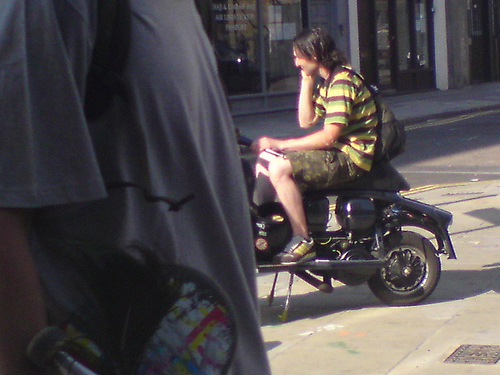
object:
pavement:
[256, 181, 500, 375]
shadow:
[259, 266, 500, 327]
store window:
[413, 0, 431, 70]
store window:
[394, 0, 412, 71]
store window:
[374, 0, 394, 87]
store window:
[260, 0, 306, 93]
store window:
[210, 0, 263, 97]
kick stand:
[277, 269, 296, 322]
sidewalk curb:
[397, 103, 500, 126]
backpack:
[81, 0, 133, 124]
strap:
[81, 0, 133, 125]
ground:
[232, 80, 500, 375]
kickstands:
[266, 266, 279, 306]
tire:
[366, 230, 442, 307]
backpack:
[339, 64, 407, 167]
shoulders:
[329, 68, 355, 90]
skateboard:
[25, 265, 238, 375]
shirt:
[312, 64, 379, 172]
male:
[248, 26, 379, 265]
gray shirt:
[0, 0, 271, 375]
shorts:
[279, 146, 368, 197]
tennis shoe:
[272, 234, 318, 265]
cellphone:
[294, 58, 303, 71]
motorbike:
[232, 126, 457, 323]